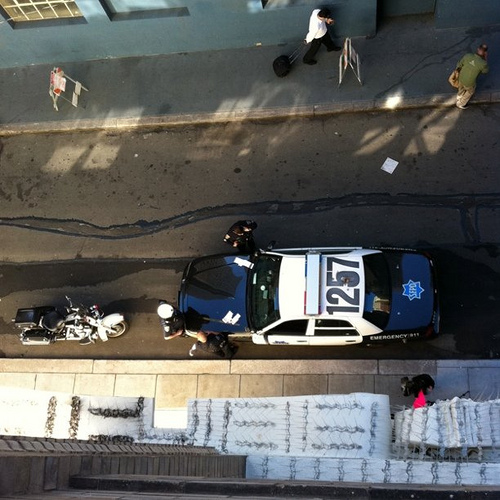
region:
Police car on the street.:
[174, 241, 438, 347]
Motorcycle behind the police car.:
[8, 301, 130, 346]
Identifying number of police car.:
[324, 258, 361, 315]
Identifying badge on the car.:
[401, 278, 426, 302]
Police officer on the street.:
[156, 302, 190, 344]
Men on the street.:
[185, 8, 486, 115]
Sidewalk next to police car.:
[1, 353, 495, 417]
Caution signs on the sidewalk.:
[41, 32, 368, 109]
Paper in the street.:
[381, 150, 403, 176]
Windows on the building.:
[2, 0, 293, 26]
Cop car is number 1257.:
[300, 264, 391, 380]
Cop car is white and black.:
[186, 259, 449, 340]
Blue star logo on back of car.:
[390, 275, 416, 306]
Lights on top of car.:
[297, 245, 330, 347]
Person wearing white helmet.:
[153, 285, 190, 356]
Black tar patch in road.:
[77, 197, 298, 229]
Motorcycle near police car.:
[3, 291, 261, 361]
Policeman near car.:
[220, 201, 280, 306]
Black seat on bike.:
[36, 307, 74, 352]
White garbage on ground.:
[371, 151, 426, 220]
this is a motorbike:
[26, 303, 121, 346]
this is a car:
[195, 260, 421, 330]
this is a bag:
[272, 52, 296, 78]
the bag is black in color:
[276, 56, 290, 74]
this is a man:
[305, 8, 332, 56]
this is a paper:
[384, 150, 395, 172]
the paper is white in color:
[383, 156, 393, 173]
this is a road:
[91, 139, 184, 226]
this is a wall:
[124, 22, 262, 46]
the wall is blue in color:
[159, 18, 204, 47]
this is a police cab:
[225, 239, 440, 346]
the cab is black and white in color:
[260, 248, 437, 340]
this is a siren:
[297, 255, 325, 314]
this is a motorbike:
[8, 292, 127, 346]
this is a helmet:
[157, 305, 172, 315]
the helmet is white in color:
[157, 302, 172, 317]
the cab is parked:
[277, 250, 435, 334]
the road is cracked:
[350, 180, 410, 223]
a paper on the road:
[373, 151, 405, 175]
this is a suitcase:
[273, 48, 298, 78]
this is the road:
[157, 135, 322, 191]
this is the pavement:
[136, 52, 235, 97]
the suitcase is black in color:
[270, 57, 290, 74]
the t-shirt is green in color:
[461, 68, 474, 84]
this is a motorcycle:
[13, 295, 126, 344]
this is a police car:
[182, 252, 444, 337]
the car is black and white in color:
[230, 265, 302, 305]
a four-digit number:
[323, 254, 358, 319]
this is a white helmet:
[155, 306, 172, 316]